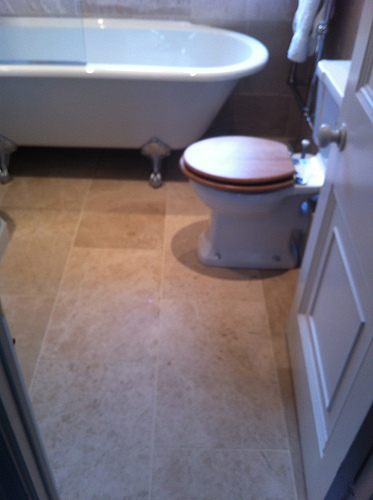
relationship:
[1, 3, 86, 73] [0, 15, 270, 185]
spray shield on edge of tub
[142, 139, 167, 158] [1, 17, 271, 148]
metal claw on bathtub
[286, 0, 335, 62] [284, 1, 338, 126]
towel on rack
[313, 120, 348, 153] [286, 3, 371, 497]
door knob on door